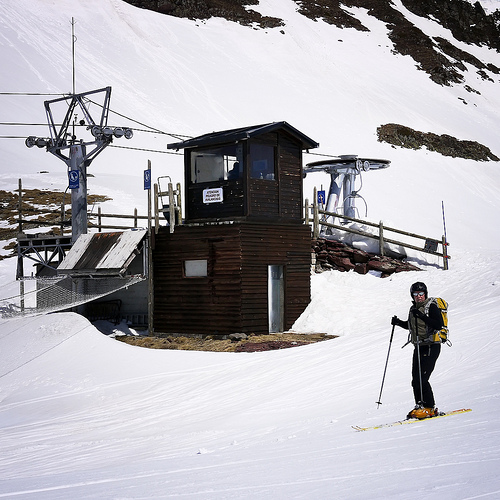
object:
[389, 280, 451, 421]
skier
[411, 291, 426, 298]
goggles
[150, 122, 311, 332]
building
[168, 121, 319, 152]
roof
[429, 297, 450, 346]
backpack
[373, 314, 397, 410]
ski pole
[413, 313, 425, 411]
ski pole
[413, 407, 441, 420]
snow shoe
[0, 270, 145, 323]
net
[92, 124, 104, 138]
roller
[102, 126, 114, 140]
roller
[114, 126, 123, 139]
roller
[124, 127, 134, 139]
roller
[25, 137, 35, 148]
roller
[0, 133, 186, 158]
cable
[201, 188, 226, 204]
sign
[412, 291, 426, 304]
face